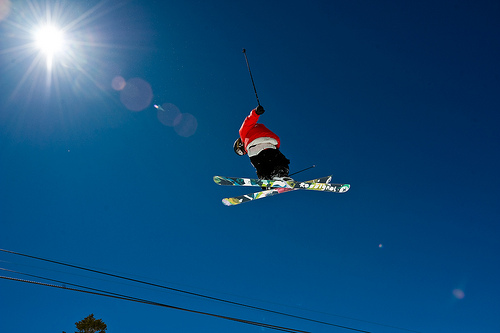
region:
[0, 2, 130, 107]
The sun is shining.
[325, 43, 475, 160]
The sky is blue.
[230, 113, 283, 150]
A red jacket.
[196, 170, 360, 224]
Two skis.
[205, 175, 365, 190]
One ski.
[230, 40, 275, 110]
One ski pole is straight up in the air.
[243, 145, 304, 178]
The person is wearing black pants.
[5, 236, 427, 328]
Power lines.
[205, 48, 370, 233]
A person is in the air.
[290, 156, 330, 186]
The person is holding onto a ski pole.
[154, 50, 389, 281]
a skier doing tricks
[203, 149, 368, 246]
the skis are multicolored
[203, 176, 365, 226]
the skis are very pretty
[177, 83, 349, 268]
the skier is in a red jacket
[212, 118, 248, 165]
the skier has on a black helmet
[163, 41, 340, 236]
the skier has a pole in each hand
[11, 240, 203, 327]
wires are in the lower part of the photo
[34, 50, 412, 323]
surely the skier is going to miss the wires!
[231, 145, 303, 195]
the skier has on black pants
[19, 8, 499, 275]
the sun is shining & the sky is brilliantly blue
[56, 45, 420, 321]
picture taken outdoors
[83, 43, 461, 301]
the sun is high up in the sky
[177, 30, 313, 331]
a skier is in the air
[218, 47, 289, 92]
the skier's pole is up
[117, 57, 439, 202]
the skier is wearing a red coat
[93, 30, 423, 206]
the picture is taken from underneath the skier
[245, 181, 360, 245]
the skis are crossed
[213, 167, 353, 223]
the skier is wearing black pants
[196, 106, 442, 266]
the skier is flying in the air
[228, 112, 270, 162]
Person wearing red coat.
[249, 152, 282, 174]
Person wearing black pants.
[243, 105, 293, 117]
Person wearing black gloves.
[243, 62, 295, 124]
Person holding ski pole in hand.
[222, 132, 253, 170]
Person wearing ski goggles on face.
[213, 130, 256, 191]
Person wearing black helmet.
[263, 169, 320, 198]
Person wearing ski boots.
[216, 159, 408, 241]
Person wearing 2 skis on feet.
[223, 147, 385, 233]
Skis are multi colored on bottom.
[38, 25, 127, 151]
Sun is shining bright in sky.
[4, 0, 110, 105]
the sun is bright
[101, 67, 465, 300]
the sun is making spots on the picture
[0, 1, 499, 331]
the clear sky is blue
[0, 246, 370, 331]
the power lines are under the skier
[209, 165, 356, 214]
the man is wearing skis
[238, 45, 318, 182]
the man is holding poles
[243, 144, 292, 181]
the man is wearing black pants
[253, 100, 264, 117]
the man is wearing black gloves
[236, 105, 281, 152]
the man is wearing a red jacket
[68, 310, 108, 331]
the top of a tree